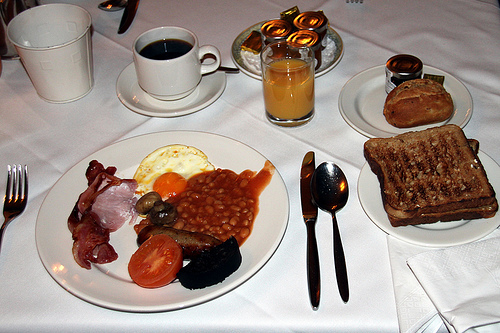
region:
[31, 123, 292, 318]
The plate is white.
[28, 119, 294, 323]
The plate is full.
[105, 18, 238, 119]
The coffee cup is full.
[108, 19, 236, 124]
The coffee cup is white.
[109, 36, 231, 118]
The saucer is round.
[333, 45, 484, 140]
The saucer is round.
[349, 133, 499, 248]
The saucer is round.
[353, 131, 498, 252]
The saucer is white.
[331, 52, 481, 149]
The saucer is white.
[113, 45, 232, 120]
The saucer is white.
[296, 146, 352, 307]
stainless steel spoon and knife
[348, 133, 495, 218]
order of grilled toast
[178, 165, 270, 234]
saucy baked beans next to eggs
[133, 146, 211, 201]
one egg made overeasy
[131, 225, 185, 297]
a slice of tomato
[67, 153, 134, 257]
fried bacon and ham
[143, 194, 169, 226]
slices of jalapeno peppers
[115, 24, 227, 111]
cup of black coffee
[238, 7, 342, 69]
a saucer of jams and a pad of butter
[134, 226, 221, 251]
a breakfast sausage link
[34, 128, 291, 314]
white plate sitting on the table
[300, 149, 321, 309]
knife on white tablecloth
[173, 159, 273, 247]
baked beans on white plate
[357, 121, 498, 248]
toasted bread on white saucer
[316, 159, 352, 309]
spoon next to the knife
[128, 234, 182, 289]
red tomato on the white plate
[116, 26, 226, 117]
white cup on white saucer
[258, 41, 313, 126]
glass with juice in it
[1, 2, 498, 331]
white cloth covering the table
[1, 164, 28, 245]
fork lying on the table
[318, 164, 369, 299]
a spoon on the table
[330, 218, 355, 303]
the handle of a spoon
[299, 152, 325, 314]
the knife on the table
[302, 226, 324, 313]
the handle of a knife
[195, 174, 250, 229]
beans on a plate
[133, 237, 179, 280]
a piece of red tomato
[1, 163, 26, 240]
a fork on the table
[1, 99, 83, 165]
a white table cloth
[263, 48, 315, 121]
a glass with juice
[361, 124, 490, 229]
this is a slice of bread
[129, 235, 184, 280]
this is a slice of tomato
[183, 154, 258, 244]
these are beans in soup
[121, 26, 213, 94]
this is a cup of coffe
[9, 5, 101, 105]
this is a plastic cup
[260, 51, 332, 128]
this is a glass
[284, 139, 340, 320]
this is a knife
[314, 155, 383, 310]
this is a spoon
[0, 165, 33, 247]
this is a fork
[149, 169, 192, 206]
this is an egg